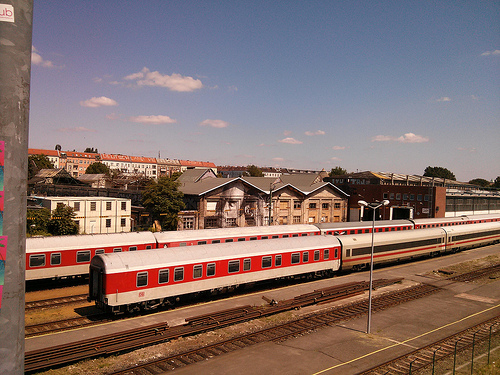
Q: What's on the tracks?
A: Trains.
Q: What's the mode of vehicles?
A: Trains.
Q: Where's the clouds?
A: In the sky.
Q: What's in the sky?
A: Clouds.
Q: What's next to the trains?
A: Buildings.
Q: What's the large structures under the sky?
A: Buildings.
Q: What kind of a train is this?
A: This train is white and silver.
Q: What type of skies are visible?
A: Blue skies with a hint of clouds.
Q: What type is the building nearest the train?
A: The building is white in color.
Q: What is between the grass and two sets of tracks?
A: Asphalt.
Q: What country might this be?
A: United States.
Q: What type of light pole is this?
A: This light pole is bright silver.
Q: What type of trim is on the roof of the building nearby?
A: Light blue trim is on the roof.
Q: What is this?
A: A train.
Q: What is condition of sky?
A: Clear.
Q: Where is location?
A: In the city.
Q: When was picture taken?
A: During daylight.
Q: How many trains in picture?
A: Two.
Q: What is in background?
A: Buildings.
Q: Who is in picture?
A: No one.